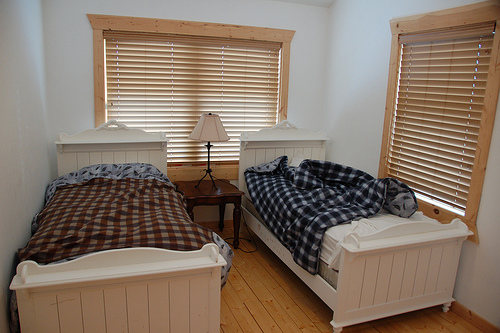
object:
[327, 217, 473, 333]
foot board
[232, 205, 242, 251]
stand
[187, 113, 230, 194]
lamp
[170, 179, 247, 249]
table